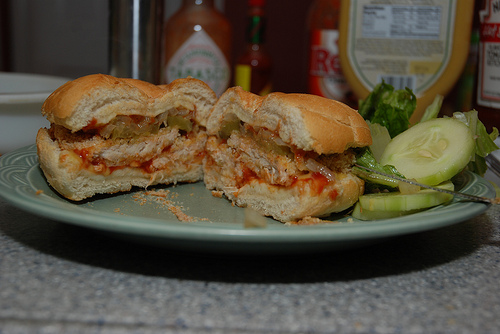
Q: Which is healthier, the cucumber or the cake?
A: The cucumber is healthier than the cake.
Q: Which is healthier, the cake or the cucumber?
A: The cucumber is healthier than the cake.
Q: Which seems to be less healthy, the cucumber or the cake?
A: The cake is less healthy than the cucumber.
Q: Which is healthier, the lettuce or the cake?
A: The lettuce is healthier than the cake.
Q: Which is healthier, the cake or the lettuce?
A: The lettuce is healthier than the cake.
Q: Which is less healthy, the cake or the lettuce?
A: The cake is less healthy than the lettuce.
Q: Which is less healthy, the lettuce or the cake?
A: The cake is less healthy than the lettuce.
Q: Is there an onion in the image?
A: Yes, there is an onion.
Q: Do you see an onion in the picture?
A: Yes, there is an onion.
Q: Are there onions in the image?
A: Yes, there is an onion.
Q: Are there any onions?
A: Yes, there is an onion.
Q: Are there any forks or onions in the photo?
A: Yes, there is an onion.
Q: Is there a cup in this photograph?
A: No, there are no cups.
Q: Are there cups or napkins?
A: No, there are no cups or napkins.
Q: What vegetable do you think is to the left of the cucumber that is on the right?
A: The vegetable is an onion.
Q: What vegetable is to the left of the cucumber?
A: The vegetable is an onion.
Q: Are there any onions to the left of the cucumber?
A: Yes, there is an onion to the left of the cucumber.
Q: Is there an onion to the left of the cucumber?
A: Yes, there is an onion to the left of the cucumber.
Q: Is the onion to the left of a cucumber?
A: Yes, the onion is to the left of a cucumber.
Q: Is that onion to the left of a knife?
A: No, the onion is to the left of a cucumber.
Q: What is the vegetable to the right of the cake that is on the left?
A: The vegetable is an onion.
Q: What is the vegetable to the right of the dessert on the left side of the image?
A: The vegetable is an onion.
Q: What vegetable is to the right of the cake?
A: The vegetable is an onion.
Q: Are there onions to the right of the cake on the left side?
A: Yes, there is an onion to the right of the cake.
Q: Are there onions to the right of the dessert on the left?
A: Yes, there is an onion to the right of the cake.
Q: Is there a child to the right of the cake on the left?
A: No, there is an onion to the right of the cake.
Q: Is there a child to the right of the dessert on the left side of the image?
A: No, there is an onion to the right of the cake.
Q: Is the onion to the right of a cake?
A: Yes, the onion is to the right of a cake.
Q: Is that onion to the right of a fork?
A: No, the onion is to the right of a cake.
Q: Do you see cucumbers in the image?
A: Yes, there is a cucumber.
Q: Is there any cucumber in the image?
A: Yes, there is a cucumber.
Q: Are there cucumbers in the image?
A: Yes, there is a cucumber.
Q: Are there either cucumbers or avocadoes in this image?
A: Yes, there is a cucumber.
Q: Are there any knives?
A: No, there are no knives.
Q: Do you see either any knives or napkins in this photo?
A: No, there are no knives or napkins.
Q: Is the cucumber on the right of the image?
A: Yes, the cucumber is on the right of the image.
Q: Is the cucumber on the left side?
A: No, the cucumber is on the right of the image.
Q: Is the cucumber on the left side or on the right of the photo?
A: The cucumber is on the right of the image.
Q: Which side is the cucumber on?
A: The cucumber is on the right of the image.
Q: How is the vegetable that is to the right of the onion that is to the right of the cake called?
A: The vegetable is a cucumber.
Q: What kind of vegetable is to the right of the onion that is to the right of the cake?
A: The vegetable is a cucumber.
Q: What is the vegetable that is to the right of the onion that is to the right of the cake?
A: The vegetable is a cucumber.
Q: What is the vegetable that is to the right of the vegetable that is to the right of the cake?
A: The vegetable is a cucumber.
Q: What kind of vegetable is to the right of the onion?
A: The vegetable is a cucumber.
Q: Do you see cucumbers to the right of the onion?
A: Yes, there is a cucumber to the right of the onion.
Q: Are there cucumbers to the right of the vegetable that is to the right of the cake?
A: Yes, there is a cucumber to the right of the onion.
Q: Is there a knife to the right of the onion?
A: No, there is a cucumber to the right of the onion.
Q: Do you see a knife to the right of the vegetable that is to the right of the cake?
A: No, there is a cucumber to the right of the onion.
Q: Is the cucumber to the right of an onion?
A: Yes, the cucumber is to the right of an onion.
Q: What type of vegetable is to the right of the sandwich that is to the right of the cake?
A: The vegetable is a cucumber.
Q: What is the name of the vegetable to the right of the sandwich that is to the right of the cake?
A: The vegetable is a cucumber.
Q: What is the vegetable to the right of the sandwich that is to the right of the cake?
A: The vegetable is a cucumber.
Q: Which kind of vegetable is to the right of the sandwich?
A: The vegetable is a cucumber.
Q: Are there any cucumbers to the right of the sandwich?
A: Yes, there is a cucumber to the right of the sandwich.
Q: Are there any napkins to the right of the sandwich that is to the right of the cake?
A: No, there is a cucumber to the right of the sandwich.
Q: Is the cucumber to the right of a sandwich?
A: Yes, the cucumber is to the right of a sandwich.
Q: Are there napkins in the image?
A: No, there are no napkins.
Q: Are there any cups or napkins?
A: No, there are no napkins or cups.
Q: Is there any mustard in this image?
A: Yes, there is mustard.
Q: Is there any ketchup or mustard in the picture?
A: Yes, there is mustard.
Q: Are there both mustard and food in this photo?
A: Yes, there are both mustard and food.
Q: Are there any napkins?
A: No, there are no napkins.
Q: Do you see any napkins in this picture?
A: No, there are no napkins.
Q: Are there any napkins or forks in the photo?
A: No, there are no napkins or forks.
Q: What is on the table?
A: The mustard is on the table.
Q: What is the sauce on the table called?
A: The sauce is mustard.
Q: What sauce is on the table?
A: The sauce is mustard.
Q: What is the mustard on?
A: The mustard is on the table.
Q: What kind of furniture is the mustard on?
A: The mustard is on the table.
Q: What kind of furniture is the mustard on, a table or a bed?
A: The mustard is on a table.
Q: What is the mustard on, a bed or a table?
A: The mustard is on a table.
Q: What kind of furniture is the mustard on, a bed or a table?
A: The mustard is on a table.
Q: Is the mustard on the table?
A: Yes, the mustard is on the table.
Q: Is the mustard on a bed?
A: No, the mustard is on the table.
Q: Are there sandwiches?
A: Yes, there is a sandwich.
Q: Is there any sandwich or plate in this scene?
A: Yes, there is a sandwich.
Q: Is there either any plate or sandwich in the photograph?
A: Yes, there is a sandwich.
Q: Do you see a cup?
A: No, there are no cups.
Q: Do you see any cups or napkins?
A: No, there are no cups or napkins.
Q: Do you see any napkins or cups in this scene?
A: No, there are no cups or napkins.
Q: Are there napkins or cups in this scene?
A: No, there are no cups or napkins.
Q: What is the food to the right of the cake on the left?
A: The food is a sandwich.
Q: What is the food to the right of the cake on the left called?
A: The food is a sandwich.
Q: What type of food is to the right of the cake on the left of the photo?
A: The food is a sandwich.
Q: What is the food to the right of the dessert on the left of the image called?
A: The food is a sandwich.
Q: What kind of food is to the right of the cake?
A: The food is a sandwich.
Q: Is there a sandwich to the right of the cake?
A: Yes, there is a sandwich to the right of the cake.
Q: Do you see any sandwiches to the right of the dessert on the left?
A: Yes, there is a sandwich to the right of the cake.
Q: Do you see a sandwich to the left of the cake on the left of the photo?
A: No, the sandwich is to the right of the cake.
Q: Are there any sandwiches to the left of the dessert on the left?
A: No, the sandwich is to the right of the cake.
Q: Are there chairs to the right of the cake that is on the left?
A: No, there is a sandwich to the right of the cake.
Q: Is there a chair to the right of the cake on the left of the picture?
A: No, there is a sandwich to the right of the cake.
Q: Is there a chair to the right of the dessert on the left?
A: No, there is a sandwich to the right of the cake.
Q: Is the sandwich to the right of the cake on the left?
A: Yes, the sandwich is to the right of the cake.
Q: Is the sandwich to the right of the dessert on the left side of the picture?
A: Yes, the sandwich is to the right of the cake.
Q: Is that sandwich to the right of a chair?
A: No, the sandwich is to the right of the cake.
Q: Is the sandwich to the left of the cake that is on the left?
A: No, the sandwich is to the right of the cake.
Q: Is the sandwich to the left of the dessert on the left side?
A: No, the sandwich is to the right of the cake.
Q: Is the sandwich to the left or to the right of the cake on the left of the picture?
A: The sandwich is to the right of the cake.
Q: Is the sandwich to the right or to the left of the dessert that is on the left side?
A: The sandwich is to the right of the cake.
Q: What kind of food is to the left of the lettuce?
A: The food is a sandwich.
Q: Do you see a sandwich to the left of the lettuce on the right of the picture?
A: Yes, there is a sandwich to the left of the lettuce.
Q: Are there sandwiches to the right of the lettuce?
A: No, the sandwich is to the left of the lettuce.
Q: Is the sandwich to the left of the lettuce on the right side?
A: Yes, the sandwich is to the left of the lettuce.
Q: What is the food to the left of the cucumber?
A: The food is a sandwich.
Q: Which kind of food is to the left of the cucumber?
A: The food is a sandwich.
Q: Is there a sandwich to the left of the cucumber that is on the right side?
A: Yes, there is a sandwich to the left of the cucumber.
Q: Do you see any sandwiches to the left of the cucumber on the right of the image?
A: Yes, there is a sandwich to the left of the cucumber.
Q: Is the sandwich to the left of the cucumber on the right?
A: Yes, the sandwich is to the left of the cucumber.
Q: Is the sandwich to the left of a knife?
A: No, the sandwich is to the left of the cucumber.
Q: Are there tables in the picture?
A: Yes, there is a table.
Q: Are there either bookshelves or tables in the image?
A: Yes, there is a table.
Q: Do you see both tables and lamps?
A: No, there is a table but no lamps.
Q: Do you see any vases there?
A: No, there are no vases.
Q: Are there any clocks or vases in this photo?
A: No, there are no vases or clocks.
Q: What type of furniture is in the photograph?
A: The furniture is a table.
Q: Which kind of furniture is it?
A: The piece of furniture is a table.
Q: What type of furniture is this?
A: This is a table.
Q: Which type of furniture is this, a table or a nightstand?
A: This is a table.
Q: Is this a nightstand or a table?
A: This is a table.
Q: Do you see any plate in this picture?
A: Yes, there is a plate.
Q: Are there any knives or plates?
A: Yes, there is a plate.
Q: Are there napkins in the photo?
A: No, there are no napkins.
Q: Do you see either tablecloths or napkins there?
A: No, there are no napkins or tablecloths.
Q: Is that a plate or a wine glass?
A: That is a plate.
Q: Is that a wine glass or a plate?
A: That is a plate.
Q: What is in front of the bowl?
A: The plate is in front of the bowl.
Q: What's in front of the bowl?
A: The plate is in front of the bowl.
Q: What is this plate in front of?
A: The plate is in front of the bowl.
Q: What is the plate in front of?
A: The plate is in front of the bowl.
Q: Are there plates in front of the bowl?
A: Yes, there is a plate in front of the bowl.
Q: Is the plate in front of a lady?
A: No, the plate is in front of the bowl.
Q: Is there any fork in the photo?
A: No, there are no forks.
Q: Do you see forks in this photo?
A: No, there are no forks.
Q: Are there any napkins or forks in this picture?
A: No, there are no forks or napkins.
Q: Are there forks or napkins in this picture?
A: No, there are no forks or napkins.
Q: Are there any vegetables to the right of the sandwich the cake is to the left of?
A: Yes, there is a vegetable to the right of the sandwich.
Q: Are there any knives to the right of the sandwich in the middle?
A: No, there is a vegetable to the right of the sandwich.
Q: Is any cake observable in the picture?
A: Yes, there is a cake.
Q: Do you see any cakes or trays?
A: Yes, there is a cake.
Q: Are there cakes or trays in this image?
A: Yes, there is a cake.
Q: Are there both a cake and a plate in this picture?
A: Yes, there are both a cake and a plate.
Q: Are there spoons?
A: No, there are no spoons.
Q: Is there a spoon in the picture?
A: No, there are no spoons.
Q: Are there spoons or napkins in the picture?
A: No, there are no spoons or napkins.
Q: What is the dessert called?
A: The dessert is a cake.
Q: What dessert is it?
A: The dessert is a cake.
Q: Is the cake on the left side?
A: Yes, the cake is on the left of the image.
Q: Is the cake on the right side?
A: No, the cake is on the left of the image.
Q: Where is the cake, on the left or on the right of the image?
A: The cake is on the left of the image.